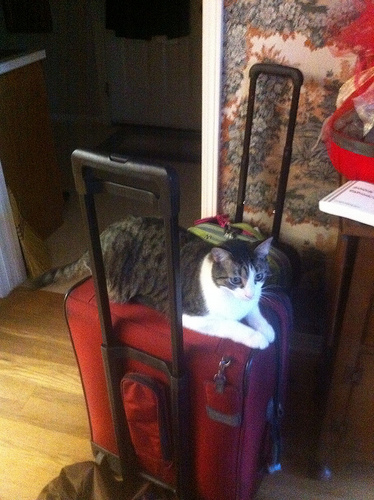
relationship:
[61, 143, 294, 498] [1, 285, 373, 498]
suitcase on floor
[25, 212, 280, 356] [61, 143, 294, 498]
cat sitting on suitcase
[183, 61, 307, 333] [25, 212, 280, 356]
suitcase behind cat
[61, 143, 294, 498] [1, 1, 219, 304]
suitcase near door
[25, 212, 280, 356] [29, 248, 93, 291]
cat has tail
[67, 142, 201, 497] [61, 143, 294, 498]
handle extended on suitcase